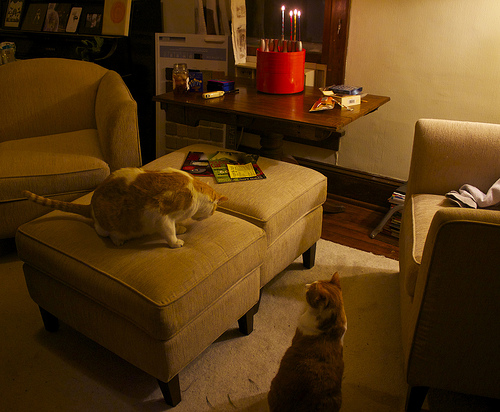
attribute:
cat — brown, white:
[266, 267, 346, 409]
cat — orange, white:
[26, 155, 218, 251]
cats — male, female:
[17, 161, 357, 405]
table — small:
[158, 49, 397, 137]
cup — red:
[258, 42, 304, 89]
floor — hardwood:
[335, 198, 401, 255]